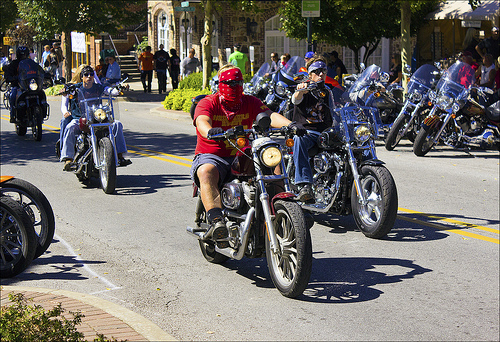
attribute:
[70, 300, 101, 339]
bricks — red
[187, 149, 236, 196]
short — gray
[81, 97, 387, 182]
headlights — on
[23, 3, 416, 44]
trees — green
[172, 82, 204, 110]
bushes — green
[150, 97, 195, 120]
corner — street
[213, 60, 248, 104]
mask — red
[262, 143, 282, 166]
light — on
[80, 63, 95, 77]
helmet — black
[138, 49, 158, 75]
shirt — orange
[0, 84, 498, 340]
street — side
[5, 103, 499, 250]
yellow line — double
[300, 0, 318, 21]
sign — green, white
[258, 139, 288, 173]
light — on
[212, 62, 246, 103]
bandana — red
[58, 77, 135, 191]
bike — blue